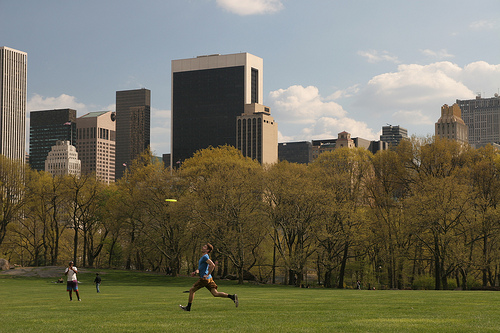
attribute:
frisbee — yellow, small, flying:
[167, 198, 177, 204]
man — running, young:
[178, 243, 238, 312]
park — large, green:
[0, 260, 494, 331]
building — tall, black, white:
[172, 54, 264, 177]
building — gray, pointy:
[76, 110, 115, 192]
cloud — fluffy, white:
[269, 86, 346, 120]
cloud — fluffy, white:
[371, 69, 480, 98]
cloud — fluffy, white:
[321, 116, 374, 144]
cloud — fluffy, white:
[219, 1, 283, 13]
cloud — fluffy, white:
[29, 93, 84, 113]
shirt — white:
[63, 265, 78, 282]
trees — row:
[0, 132, 500, 289]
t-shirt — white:
[63, 266, 77, 281]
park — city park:
[50, 129, 447, 313]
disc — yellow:
[165, 196, 175, 203]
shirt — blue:
[194, 249, 214, 279]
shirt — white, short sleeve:
[62, 260, 79, 282]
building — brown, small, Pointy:
[425, 91, 469, 160]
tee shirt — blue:
[191, 256, 214, 278]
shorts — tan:
[183, 271, 221, 292]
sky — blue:
[1, 0, 499, 159]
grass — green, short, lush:
[5, 270, 497, 330]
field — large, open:
[5, 274, 497, 331]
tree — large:
[450, 142, 498, 288]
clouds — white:
[274, 56, 442, 127]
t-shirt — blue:
[188, 252, 223, 284]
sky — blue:
[2, 6, 484, 86]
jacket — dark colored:
[91, 274, 107, 285]